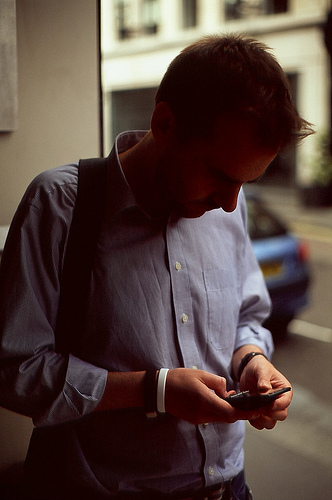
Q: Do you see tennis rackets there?
A: No, there are no tennis rackets.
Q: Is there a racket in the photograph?
A: No, there are no rackets.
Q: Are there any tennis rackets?
A: No, there are no tennis rackets.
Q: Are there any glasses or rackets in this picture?
A: No, there are no rackets or glasses.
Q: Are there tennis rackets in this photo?
A: No, there are no tennis rackets.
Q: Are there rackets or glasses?
A: No, there are no rackets or glasses.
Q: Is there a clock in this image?
A: No, there are no clocks.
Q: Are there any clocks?
A: No, there are no clocks.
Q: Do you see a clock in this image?
A: No, there are no clocks.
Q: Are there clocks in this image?
A: No, there are no clocks.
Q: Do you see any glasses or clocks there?
A: No, there are no clocks or glasses.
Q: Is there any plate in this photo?
A: Yes, there is a plate.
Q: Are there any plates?
A: Yes, there is a plate.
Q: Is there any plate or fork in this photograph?
A: Yes, there is a plate.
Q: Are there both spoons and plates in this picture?
A: No, there is a plate but no spoons.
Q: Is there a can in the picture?
A: No, there are no cans.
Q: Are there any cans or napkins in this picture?
A: No, there are no cans or napkins.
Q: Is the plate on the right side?
A: Yes, the plate is on the right of the image.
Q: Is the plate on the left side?
A: No, the plate is on the right of the image.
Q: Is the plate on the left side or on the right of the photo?
A: The plate is on the right of the image.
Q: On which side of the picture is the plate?
A: The plate is on the right of the image.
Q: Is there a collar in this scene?
A: Yes, there is a collar.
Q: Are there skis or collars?
A: Yes, there is a collar.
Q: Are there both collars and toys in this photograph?
A: No, there is a collar but no toys.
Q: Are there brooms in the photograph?
A: No, there are no brooms.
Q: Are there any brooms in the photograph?
A: No, there are no brooms.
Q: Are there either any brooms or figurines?
A: No, there are no brooms or figurines.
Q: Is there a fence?
A: No, there are no fences.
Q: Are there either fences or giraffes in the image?
A: No, there are no fences or giraffes.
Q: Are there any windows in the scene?
A: Yes, there is a window.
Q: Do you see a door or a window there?
A: Yes, there is a window.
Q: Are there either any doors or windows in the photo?
A: Yes, there is a window.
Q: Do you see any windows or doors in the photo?
A: Yes, there is a window.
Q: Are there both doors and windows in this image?
A: No, there is a window but no doors.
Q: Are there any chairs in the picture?
A: No, there are no chairs.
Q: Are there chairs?
A: No, there are no chairs.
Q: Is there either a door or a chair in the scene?
A: No, there are no chairs or doors.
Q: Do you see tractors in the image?
A: No, there are no tractors.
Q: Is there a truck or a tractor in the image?
A: No, there are no tractors or trucks.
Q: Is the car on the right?
A: Yes, the car is on the right of the image.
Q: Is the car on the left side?
A: No, the car is on the right of the image.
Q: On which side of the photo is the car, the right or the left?
A: The car is on the right of the image.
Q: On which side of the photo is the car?
A: The car is on the right of the image.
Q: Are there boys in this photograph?
A: No, there are no boys.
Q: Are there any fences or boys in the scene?
A: No, there are no boys or fences.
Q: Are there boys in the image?
A: No, there are no boys.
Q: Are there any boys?
A: No, there are no boys.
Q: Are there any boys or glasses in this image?
A: No, there are no boys or glasses.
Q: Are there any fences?
A: No, there are no fences.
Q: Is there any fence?
A: No, there are no fences.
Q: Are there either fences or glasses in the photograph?
A: No, there are no fences or glasses.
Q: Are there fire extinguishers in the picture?
A: No, there are no fire extinguishers.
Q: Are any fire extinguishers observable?
A: No, there are no fire extinguishers.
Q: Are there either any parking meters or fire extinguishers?
A: No, there are no fire extinguishers or parking meters.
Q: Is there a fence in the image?
A: No, there are no fences.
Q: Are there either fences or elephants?
A: No, there are no fences or elephants.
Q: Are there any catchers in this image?
A: No, there are no catchers.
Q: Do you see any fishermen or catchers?
A: No, there are no catchers or fishermen.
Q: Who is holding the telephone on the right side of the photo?
A: The man is holding the telephone.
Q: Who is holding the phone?
A: The man is holding the telephone.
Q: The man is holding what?
A: The man is holding the telephone.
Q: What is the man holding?
A: The man is holding the telephone.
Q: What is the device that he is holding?
A: The device is a phone.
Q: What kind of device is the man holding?
A: The man is holding the phone.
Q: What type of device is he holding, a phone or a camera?
A: The man is holding a phone.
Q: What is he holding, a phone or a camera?
A: The man is holding a phone.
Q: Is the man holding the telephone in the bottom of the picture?
A: Yes, the man is holding the phone.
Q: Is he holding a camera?
A: No, the man is holding the phone.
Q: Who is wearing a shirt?
A: The man is wearing a shirt.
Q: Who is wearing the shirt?
A: The man is wearing a shirt.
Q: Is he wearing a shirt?
A: Yes, the man is wearing a shirt.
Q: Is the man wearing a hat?
A: No, the man is wearing a shirt.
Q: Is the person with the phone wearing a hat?
A: No, the man is wearing a shirt.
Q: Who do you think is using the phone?
A: The man is using the phone.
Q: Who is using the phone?
A: The man is using the phone.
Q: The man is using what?
A: The man is using a telephone.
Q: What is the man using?
A: The man is using a telephone.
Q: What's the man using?
A: The man is using a telephone.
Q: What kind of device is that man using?
A: The man is using a telephone.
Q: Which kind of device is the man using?
A: The man is using a telephone.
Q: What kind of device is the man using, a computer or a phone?
A: The man is using a phone.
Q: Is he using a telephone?
A: Yes, the man is using a telephone.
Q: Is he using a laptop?
A: No, the man is using a telephone.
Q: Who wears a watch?
A: The man wears a watch.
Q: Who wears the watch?
A: The man wears a watch.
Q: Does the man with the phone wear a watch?
A: Yes, the man wears a watch.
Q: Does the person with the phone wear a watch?
A: Yes, the man wears a watch.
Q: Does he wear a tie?
A: No, the man wears a watch.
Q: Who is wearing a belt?
A: The man is wearing a belt.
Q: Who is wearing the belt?
A: The man is wearing a belt.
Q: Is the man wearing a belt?
A: Yes, the man is wearing a belt.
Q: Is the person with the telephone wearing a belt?
A: Yes, the man is wearing a belt.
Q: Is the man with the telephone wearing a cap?
A: No, the man is wearing a belt.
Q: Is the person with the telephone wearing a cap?
A: No, the man is wearing a belt.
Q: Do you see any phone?
A: Yes, there is a phone.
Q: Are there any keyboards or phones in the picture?
A: Yes, there is a phone.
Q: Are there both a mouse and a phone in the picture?
A: No, there is a phone but no computer mice.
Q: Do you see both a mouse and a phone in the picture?
A: No, there is a phone but no computer mice.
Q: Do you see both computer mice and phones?
A: No, there is a phone but no computer mice.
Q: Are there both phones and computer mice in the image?
A: No, there is a phone but no computer mice.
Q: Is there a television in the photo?
A: No, there are no televisions.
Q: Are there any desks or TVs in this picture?
A: No, there are no TVs or desks.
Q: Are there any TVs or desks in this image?
A: No, there are no TVs or desks.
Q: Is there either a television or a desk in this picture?
A: No, there are no televisions or desks.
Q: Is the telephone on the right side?
A: Yes, the telephone is on the right of the image.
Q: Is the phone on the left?
A: No, the phone is on the right of the image.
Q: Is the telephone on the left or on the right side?
A: The telephone is on the right of the image.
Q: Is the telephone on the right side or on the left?
A: The telephone is on the right of the image.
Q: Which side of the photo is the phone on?
A: The phone is on the right of the image.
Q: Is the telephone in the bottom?
A: Yes, the telephone is in the bottom of the image.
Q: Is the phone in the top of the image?
A: No, the phone is in the bottom of the image.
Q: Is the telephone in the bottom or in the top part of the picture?
A: The telephone is in the bottom of the image.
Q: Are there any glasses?
A: No, there are no glasses.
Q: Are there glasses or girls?
A: No, there are no glasses or girls.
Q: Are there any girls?
A: No, there are no girls.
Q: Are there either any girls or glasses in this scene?
A: No, there are no girls or glasses.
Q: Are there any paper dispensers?
A: No, there are no paper dispensers.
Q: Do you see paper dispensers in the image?
A: No, there are no paper dispensers.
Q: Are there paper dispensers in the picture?
A: No, there are no paper dispensers.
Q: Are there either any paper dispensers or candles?
A: No, there are no paper dispensers or candles.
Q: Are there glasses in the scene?
A: No, there are no glasses.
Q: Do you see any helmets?
A: No, there are no helmets.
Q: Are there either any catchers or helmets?
A: No, there are no helmets or catchers.